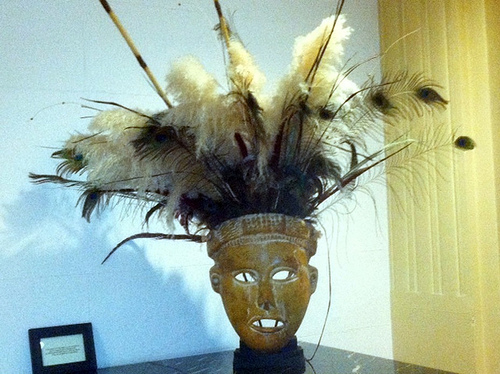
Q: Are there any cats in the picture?
A: No, there are no cats.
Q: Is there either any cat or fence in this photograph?
A: No, there are no cats or fences.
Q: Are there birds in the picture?
A: No, there are no birds.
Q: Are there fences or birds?
A: No, there are no birds or fences.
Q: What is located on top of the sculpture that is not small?
A: The feathers are on top of the sculpture.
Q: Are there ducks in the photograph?
A: No, there are no ducks.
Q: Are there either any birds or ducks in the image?
A: No, there are no ducks or birds.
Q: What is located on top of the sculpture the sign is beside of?
A: The feathers are on top of the sculpture.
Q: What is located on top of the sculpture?
A: The feathers are on top of the sculpture.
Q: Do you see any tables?
A: Yes, there is a table.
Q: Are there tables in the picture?
A: Yes, there is a table.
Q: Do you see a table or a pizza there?
A: Yes, there is a table.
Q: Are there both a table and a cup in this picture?
A: No, there is a table but no cups.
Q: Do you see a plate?
A: No, there are no plates.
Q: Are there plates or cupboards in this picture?
A: No, there are no plates or cupboards.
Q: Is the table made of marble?
A: Yes, the table is made of marble.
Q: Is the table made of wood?
A: No, the table is made of marble.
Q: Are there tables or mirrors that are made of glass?
A: No, there is a table but it is made of marble.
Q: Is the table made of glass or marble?
A: The table is made of marble.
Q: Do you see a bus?
A: No, there are no buses.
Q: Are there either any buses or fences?
A: No, there are no buses or fences.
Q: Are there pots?
A: No, there are no pots.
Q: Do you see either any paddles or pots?
A: No, there are no pots or paddles.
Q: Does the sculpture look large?
A: Yes, the sculpture is large.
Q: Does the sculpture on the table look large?
A: Yes, the sculpture is large.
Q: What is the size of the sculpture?
A: The sculpture is large.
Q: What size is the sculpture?
A: The sculpture is large.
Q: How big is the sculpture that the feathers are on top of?
A: The sculpture is large.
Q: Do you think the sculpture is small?
A: No, the sculpture is large.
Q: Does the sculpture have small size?
A: No, the sculpture is large.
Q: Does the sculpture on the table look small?
A: No, the sculpture is large.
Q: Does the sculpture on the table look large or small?
A: The sculpture is large.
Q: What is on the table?
A: The sculpture is on the table.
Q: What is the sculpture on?
A: The sculpture is on the table.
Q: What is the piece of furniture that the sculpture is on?
A: The piece of furniture is a table.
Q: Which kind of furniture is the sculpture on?
A: The sculpture is on the table.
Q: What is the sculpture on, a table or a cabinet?
A: The sculpture is on a table.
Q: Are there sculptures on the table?
A: Yes, there is a sculpture on the table.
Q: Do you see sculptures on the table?
A: Yes, there is a sculpture on the table.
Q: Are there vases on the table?
A: No, there is a sculpture on the table.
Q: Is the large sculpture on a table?
A: Yes, the sculpture is on a table.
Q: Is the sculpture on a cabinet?
A: No, the sculpture is on a table.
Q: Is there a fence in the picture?
A: No, there are no fences.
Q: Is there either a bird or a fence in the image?
A: No, there are no fences or birds.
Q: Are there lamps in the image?
A: No, there are no lamps.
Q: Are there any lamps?
A: No, there are no lamps.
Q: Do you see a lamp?
A: No, there are no lamps.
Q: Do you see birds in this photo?
A: No, there are no birds.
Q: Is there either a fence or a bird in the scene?
A: No, there are no birds or fences.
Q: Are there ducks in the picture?
A: No, there are no ducks.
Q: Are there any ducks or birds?
A: No, there are no ducks or birds.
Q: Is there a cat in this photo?
A: No, there are no cats.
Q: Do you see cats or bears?
A: No, there are no cats or bears.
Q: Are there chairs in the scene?
A: No, there are no chairs.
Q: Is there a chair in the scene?
A: No, there are no chairs.